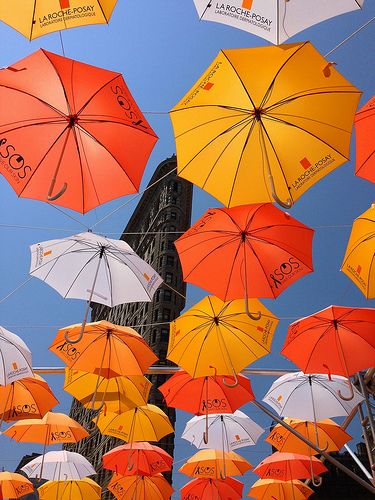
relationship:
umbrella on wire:
[32, 222, 163, 343] [91, 166, 175, 228]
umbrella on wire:
[173, 201, 315, 318] [99, 224, 187, 240]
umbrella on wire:
[175, 38, 355, 195] [91, 166, 175, 228]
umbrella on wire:
[0, 46, 159, 213] [91, 166, 175, 228]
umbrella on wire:
[159, 288, 281, 395] [91, 166, 175, 228]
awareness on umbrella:
[271, 262, 297, 287] [1, 71, 349, 388]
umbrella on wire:
[20, 449, 96, 500] [5, 303, 313, 367]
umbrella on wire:
[147, 286, 287, 400] [1, 303, 321, 354]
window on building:
[130, 301, 142, 324] [84, 162, 209, 421]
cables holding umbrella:
[11, 125, 281, 380] [354, 94, 375, 184]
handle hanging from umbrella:
[237, 285, 262, 325] [171, 202, 324, 302]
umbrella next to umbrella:
[26, 218, 172, 350] [159, 288, 281, 395]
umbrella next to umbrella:
[152, 21, 362, 211] [161, 290, 284, 388]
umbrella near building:
[107, 470, 173, 498] [58, 152, 191, 495]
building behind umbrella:
[58, 152, 191, 495] [0, 325, 35, 388]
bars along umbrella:
[203, 380, 209, 445] [0, 0, 116, 42]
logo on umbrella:
[285, 149, 336, 194] [0, 0, 116, 42]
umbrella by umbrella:
[261, 371, 367, 452] [168, 40, 362, 209]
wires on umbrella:
[0, 19, 375, 342] [0, 0, 116, 42]